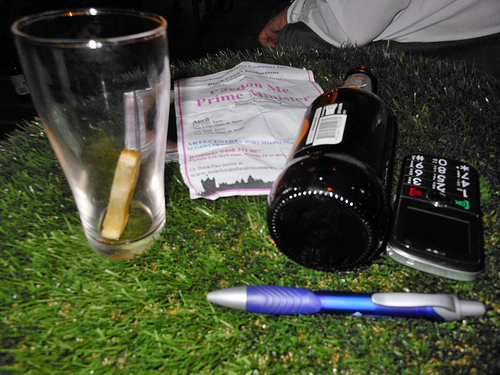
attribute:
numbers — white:
[436, 157, 447, 167]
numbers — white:
[412, 159, 425, 169]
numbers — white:
[459, 168, 472, 180]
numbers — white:
[413, 167, 421, 177]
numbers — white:
[437, 172, 445, 184]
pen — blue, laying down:
[199, 266, 496, 333]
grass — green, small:
[330, 335, 362, 372]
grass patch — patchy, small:
[45, 272, 185, 372]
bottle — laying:
[277, 52, 391, 283]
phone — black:
[397, 132, 499, 314]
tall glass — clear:
[9, 6, 172, 256]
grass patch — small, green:
[231, 329, 418, 361]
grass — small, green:
[2, 46, 499, 373]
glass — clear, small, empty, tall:
[9, 3, 173, 262]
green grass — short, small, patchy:
[1, 44, 498, 374]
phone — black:
[400, 130, 487, 280]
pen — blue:
[195, 278, 488, 337]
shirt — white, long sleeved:
[284, 3, 498, 55]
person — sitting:
[261, 0, 498, 72]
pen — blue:
[201, 277, 439, 336]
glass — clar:
[26, 41, 166, 178]